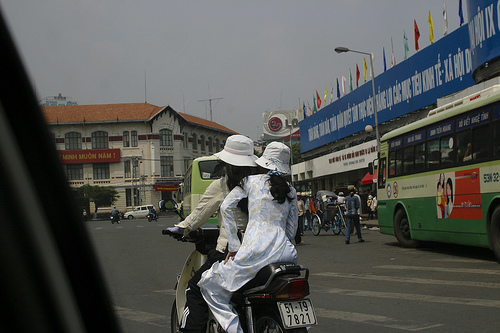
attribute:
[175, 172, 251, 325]
jacket — cream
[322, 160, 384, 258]
bike — blue 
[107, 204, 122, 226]
man motorcycle — riding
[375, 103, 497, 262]
bus — green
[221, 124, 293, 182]
hats — white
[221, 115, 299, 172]
hats — white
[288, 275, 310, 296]
tail light — red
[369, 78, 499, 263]
bus — carrying, white 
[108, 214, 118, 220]
scooter — white, red